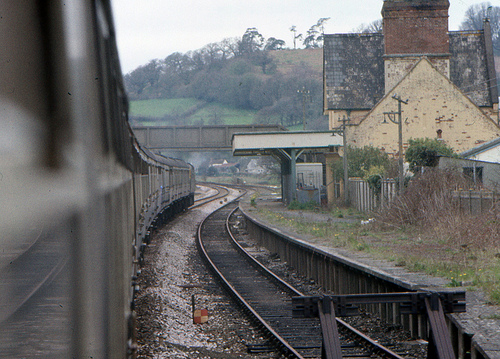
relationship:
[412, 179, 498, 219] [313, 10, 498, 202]
fence near building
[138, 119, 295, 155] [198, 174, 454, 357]
bridge on tracks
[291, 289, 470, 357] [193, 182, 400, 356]
barricade on tracks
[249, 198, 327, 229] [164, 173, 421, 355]
dandelions line track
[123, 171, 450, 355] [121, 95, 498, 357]
stones on ground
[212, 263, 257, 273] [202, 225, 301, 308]
wood on tracks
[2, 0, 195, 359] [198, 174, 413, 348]
train on track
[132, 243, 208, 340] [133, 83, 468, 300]
rocks on ground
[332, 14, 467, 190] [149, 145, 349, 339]
building near tracks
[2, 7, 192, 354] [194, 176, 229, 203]
train on tracks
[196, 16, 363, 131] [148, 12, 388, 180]
trees on hillside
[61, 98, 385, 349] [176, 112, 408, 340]
set of tracks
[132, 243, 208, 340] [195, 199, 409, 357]
rocks between tracks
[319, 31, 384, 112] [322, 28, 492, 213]
roof of building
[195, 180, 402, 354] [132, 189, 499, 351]
track on ground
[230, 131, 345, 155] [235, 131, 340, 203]
awning over patio